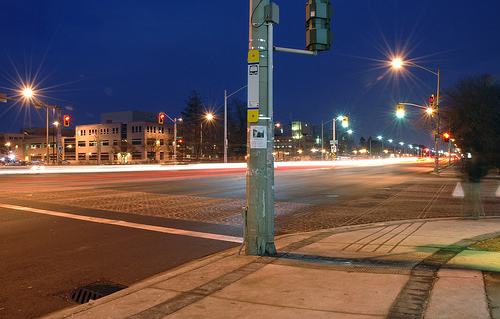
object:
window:
[101, 128, 109, 134]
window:
[121, 124, 127, 139]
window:
[147, 126, 156, 134]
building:
[75, 121, 221, 165]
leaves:
[456, 92, 473, 144]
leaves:
[461, 99, 479, 124]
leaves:
[181, 89, 209, 122]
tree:
[180, 90, 208, 157]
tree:
[222, 98, 247, 160]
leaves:
[202, 124, 224, 158]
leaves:
[465, 106, 480, 146]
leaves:
[457, 95, 481, 137]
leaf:
[466, 110, 469, 112]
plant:
[440, 72, 500, 183]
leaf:
[481, 107, 483, 108]